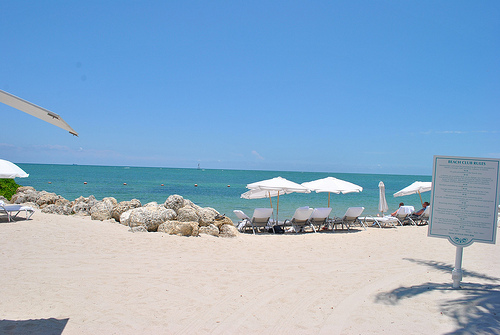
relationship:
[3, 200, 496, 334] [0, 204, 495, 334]
sand on beach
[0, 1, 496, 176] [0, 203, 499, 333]
sky above ground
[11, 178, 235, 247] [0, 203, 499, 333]
rocks on ground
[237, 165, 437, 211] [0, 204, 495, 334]
umbrellas on beach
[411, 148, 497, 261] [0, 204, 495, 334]
sign on beach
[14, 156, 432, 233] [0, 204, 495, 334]
water next to beach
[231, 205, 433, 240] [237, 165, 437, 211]
chairs under umbrellas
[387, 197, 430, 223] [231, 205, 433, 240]
people in chairs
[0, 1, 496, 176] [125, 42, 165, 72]
sky with clouds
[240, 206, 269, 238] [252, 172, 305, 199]
recliner under umbrella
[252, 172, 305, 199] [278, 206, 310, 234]
umbrella shading chair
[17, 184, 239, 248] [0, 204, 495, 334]
boulders on beach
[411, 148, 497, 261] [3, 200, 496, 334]
sign in sand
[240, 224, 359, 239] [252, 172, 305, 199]
shade unextended umbrella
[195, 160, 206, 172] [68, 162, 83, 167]
ship oil platform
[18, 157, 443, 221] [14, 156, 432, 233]
body of water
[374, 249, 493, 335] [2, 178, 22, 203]
shadow by tree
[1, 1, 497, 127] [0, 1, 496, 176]
blue clear sky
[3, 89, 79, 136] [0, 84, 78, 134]
panel of truck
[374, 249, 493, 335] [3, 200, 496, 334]
shadow by sand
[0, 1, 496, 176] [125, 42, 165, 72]
sky has clouds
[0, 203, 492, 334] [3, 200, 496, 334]
ground full of sand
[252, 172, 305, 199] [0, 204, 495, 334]
umbrella white beach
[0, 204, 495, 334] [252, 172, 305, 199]
beach white umbrella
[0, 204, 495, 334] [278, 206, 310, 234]
beach white chair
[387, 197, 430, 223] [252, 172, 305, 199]
people under umbrella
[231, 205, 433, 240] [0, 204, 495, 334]
chairs on beach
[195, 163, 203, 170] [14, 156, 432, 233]
ship on water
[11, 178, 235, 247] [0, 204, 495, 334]
rocks along beach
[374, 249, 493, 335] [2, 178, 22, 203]
shadow of tree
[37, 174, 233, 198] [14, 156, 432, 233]
floats in water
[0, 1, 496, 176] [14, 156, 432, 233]
sky over water